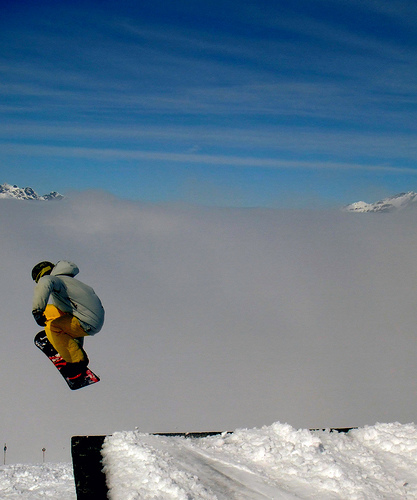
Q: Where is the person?
A: On the snowboard.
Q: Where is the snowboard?
A: Under the person.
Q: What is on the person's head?
A: A helmet.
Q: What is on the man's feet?
A: A snowboard.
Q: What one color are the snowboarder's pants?
A: Yellow.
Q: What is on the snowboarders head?
A: A helmet.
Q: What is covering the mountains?
A: Snow.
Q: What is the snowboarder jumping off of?
A: A ramp.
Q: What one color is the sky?
A: Blue.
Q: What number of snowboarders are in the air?
A: One.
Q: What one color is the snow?
A: White.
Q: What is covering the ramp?
A: Snow.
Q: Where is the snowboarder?
A: In the air.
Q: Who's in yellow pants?
A: Snow boarder.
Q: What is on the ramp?
A: Snow.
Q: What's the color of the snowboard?
A: Red and black.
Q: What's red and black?
A: Snowboard.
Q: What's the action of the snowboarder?
A: Jumping.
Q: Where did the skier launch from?
A: Ramp.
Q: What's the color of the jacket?
A: Green.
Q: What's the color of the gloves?
A: Black.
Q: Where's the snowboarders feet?
A: On the board.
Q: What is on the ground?
A: Snow.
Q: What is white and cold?
A: Snow.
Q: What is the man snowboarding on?
A: Snow.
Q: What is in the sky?
A: Clouds.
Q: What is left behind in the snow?
A: Tracks.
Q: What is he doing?
A: He's jumping.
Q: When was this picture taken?
A: In the day.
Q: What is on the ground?
A: White snow.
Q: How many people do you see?
A: Only one.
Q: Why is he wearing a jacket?
A: To stay warm.